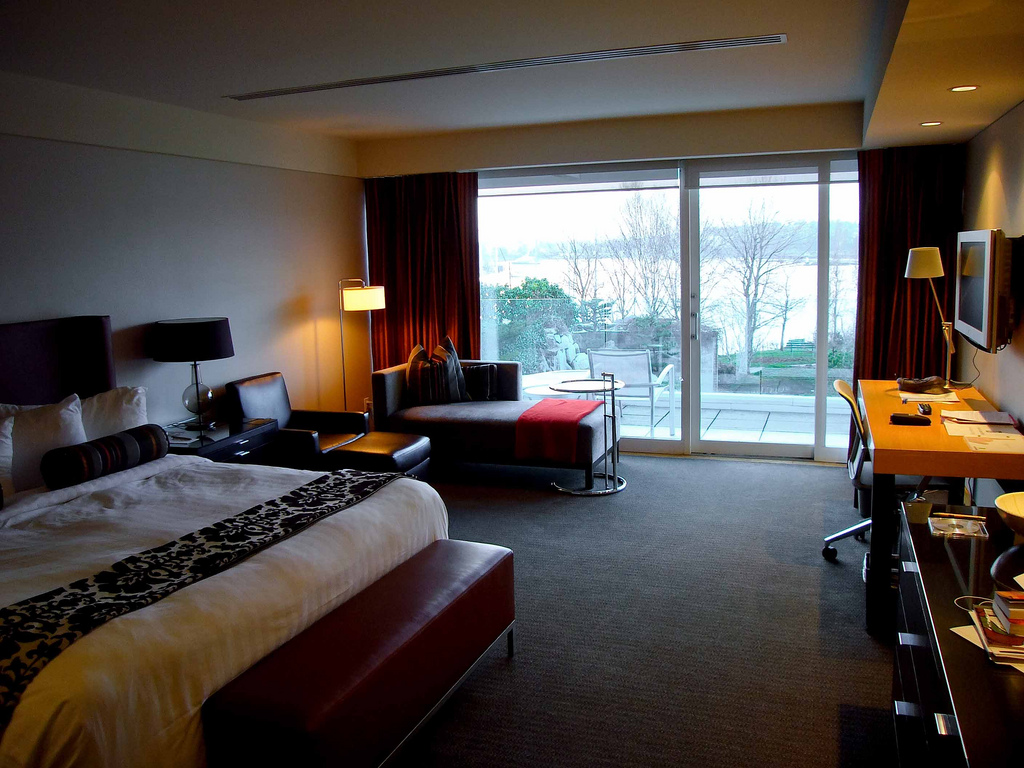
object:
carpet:
[388, 449, 891, 767]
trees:
[709, 203, 816, 374]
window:
[362, 148, 965, 463]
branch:
[562, 237, 590, 300]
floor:
[548, 496, 794, 726]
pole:
[369, 310, 374, 374]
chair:
[224, 372, 434, 481]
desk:
[857, 379, 1024, 554]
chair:
[822, 379, 946, 560]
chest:
[865, 489, 1024, 767]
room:
[0, 0, 1022, 763]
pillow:
[39, 423, 170, 489]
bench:
[198, 539, 515, 767]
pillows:
[0, 385, 150, 442]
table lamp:
[151, 317, 233, 430]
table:
[162, 415, 279, 463]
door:
[688, 154, 819, 456]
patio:
[621, 390, 853, 449]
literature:
[950, 572, 1022, 675]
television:
[955, 228, 1021, 354]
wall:
[955, 353, 1023, 427]